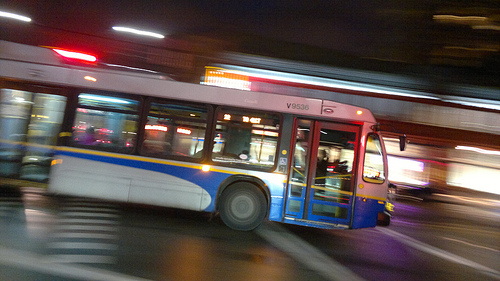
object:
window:
[364, 132, 387, 185]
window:
[209, 103, 283, 173]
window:
[68, 90, 141, 154]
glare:
[0, 56, 392, 231]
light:
[48, 48, 97, 63]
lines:
[254, 218, 369, 281]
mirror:
[399, 135, 406, 150]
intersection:
[1, 0, 498, 278]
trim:
[0, 140, 387, 230]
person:
[79, 126, 100, 145]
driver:
[317, 150, 348, 177]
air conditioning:
[0, 39, 59, 65]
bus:
[0, 39, 407, 232]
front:
[340, 104, 406, 229]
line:
[375, 225, 499, 278]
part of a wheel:
[217, 181, 269, 231]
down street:
[0, 181, 500, 281]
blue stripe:
[0, 143, 234, 213]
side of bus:
[0, 53, 379, 231]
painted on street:
[0, 182, 499, 281]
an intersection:
[443, 161, 499, 194]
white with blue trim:
[0, 139, 391, 232]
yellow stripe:
[0, 137, 387, 201]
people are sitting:
[0, 111, 261, 167]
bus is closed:
[281, 114, 364, 227]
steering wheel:
[333, 160, 347, 172]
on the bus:
[0, 40, 408, 233]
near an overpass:
[0, 0, 498, 211]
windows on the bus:
[64, 92, 283, 171]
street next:
[0, 10, 499, 207]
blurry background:
[0, 0, 127, 281]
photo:
[0, 0, 499, 280]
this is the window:
[138, 98, 209, 160]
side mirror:
[69, 91, 141, 154]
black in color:
[201, 105, 220, 161]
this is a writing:
[287, 103, 310, 110]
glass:
[210, 105, 282, 170]